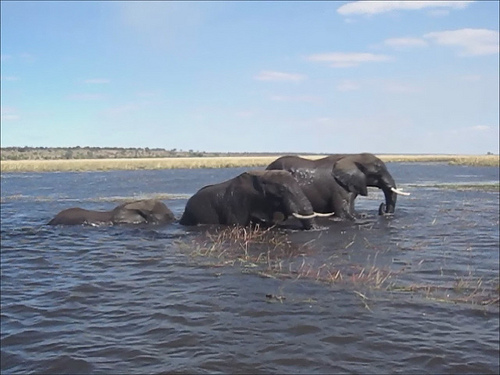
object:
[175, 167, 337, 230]
elephant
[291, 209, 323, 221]
tusk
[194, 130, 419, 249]
elephant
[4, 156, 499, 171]
vegetation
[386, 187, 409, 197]
elephant tusk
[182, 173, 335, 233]
elephant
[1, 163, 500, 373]
water